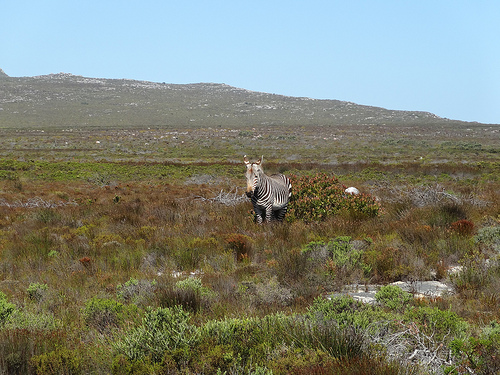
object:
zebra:
[239, 152, 298, 224]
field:
[1, 156, 500, 375]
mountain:
[0, 66, 499, 131]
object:
[344, 185, 362, 195]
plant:
[171, 269, 210, 308]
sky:
[1, 0, 500, 125]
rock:
[413, 281, 456, 297]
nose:
[245, 188, 255, 196]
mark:
[248, 162, 255, 174]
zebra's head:
[243, 154, 266, 197]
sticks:
[370, 324, 462, 373]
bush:
[277, 168, 380, 227]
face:
[243, 164, 262, 197]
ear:
[241, 153, 250, 167]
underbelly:
[272, 201, 285, 212]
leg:
[262, 205, 271, 227]